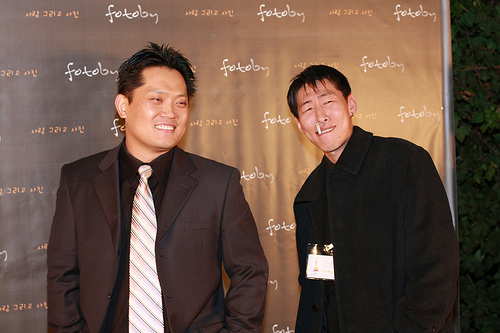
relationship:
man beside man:
[79, 29, 239, 330] [256, 43, 446, 330]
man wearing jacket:
[45, 40, 273, 333] [46, 148, 269, 332]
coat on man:
[290, 71, 455, 303] [268, 53, 385, 315]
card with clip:
[307, 250, 337, 280] [322, 239, 334, 251]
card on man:
[307, 250, 337, 280] [286, 63, 458, 331]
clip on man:
[322, 239, 334, 251] [286, 63, 458, 331]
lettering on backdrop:
[217, 56, 270, 80] [2, 4, 431, 331]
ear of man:
[105, 90, 134, 118] [45, 40, 273, 333]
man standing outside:
[268, 62, 471, 332] [3, 4, 493, 331]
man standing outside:
[45, 40, 273, 333] [3, 4, 493, 331]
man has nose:
[45, 40, 273, 333] [164, 97, 177, 121]